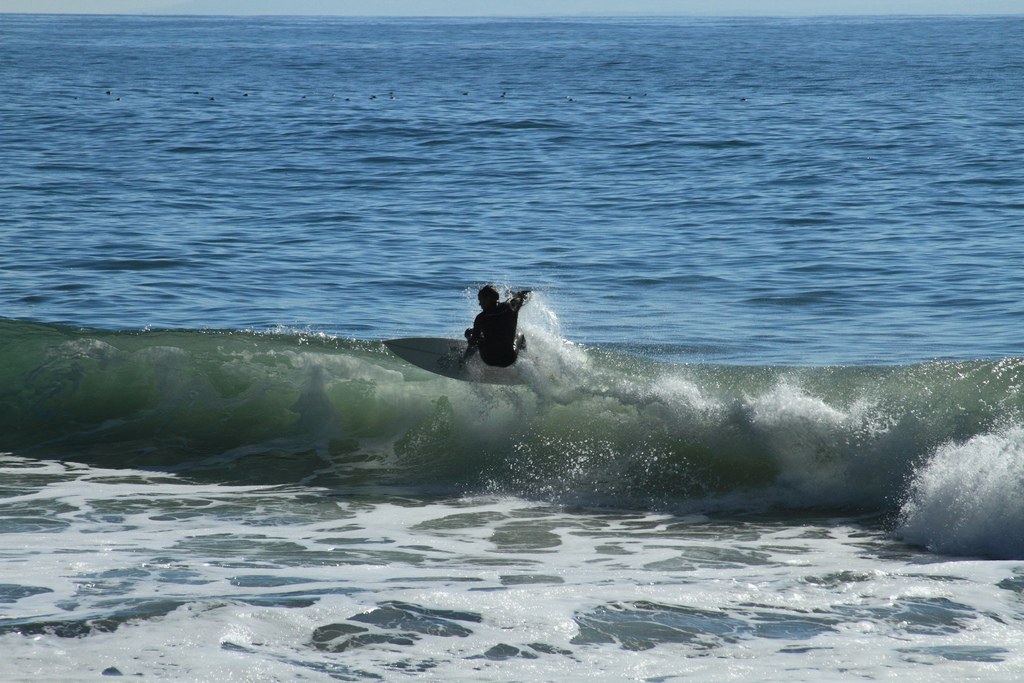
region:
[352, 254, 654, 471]
the person is surfing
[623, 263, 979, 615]
the wave is rolling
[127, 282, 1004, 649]
the waves are white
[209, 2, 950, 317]
the ocean is calm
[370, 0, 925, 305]
the water is blue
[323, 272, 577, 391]
the person is wearing black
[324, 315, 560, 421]
the surfboard is white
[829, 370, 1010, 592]
the water is splashing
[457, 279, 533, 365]
a man standing on a surfboard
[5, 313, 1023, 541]
the wave the man is riding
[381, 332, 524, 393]
the surfboard the man is riding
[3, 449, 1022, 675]
the foamy part of the water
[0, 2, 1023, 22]
the small patch of clear blue sky above the water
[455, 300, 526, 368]
the black wetsuit the man is wearing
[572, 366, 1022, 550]
the foamy top of the wave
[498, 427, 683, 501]
drops of water hitting in the air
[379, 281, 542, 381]
a surfer riding the water in the ocean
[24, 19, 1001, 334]
the calm part of the ocean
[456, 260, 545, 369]
man surfing a wave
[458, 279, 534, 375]
man surfing in the water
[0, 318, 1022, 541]
large curved open wave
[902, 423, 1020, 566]
large white frothy foam in water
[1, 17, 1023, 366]
large open body of water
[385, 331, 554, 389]
long large blue surfboard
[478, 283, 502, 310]
small round black head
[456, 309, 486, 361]
long thin black arm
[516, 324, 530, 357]
small long part of leg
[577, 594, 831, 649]
patch of grey green water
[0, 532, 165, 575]
white foam on water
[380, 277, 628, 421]
A surfer doing a trick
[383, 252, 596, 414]
A person on a surf board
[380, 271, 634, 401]
A person that is surfing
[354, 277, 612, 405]
A person riding a wave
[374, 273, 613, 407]
Surfer riding a wave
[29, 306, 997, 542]
A wave in the ocean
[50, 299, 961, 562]
salt water surfer riding it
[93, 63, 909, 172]
Many birds in the distance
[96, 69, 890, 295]
More waves coming in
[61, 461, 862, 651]
Sea foam getting stirred up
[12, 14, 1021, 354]
the calm water in the back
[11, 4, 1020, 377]
A area of calm water in the back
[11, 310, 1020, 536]
The large green wave